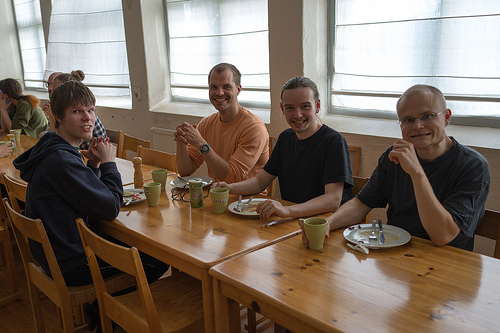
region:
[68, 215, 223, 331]
light brown wooden chair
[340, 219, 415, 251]
circular white plate on wooden table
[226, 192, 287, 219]
circular white plate on wooden table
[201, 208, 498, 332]
light brown rectangular wooden table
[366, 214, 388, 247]
silver metal knife and fork on white plate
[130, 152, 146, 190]
light brown wooden salt shaker on wooden table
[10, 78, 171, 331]
man wearing blue jacket and jeans sitting at wooden table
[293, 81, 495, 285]
man sitting at table holding cup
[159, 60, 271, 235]
man in light orange shirt sitting at wooden table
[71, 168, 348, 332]
rectangular light brown wooden table next to table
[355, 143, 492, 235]
the shirt is black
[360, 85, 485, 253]
the man has glasses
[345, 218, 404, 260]
the plate is on the table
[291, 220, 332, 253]
the cup is brown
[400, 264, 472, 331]
shadow is on the table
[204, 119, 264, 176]
the shirt is orange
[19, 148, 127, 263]
the jumper is blue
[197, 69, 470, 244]
the people are sitted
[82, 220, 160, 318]
the chair is wooden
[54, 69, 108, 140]
the woman is sitted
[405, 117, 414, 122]
The lens of glasses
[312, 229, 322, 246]
A cup on the table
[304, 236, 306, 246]
Fingers wrapped around a cup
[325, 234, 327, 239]
A thumb on the cup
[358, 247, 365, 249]
Paper napkin on the table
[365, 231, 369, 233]
Left over sauce on the plate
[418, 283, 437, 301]
Shadow cast by man on the table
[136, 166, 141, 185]
A salt shaker on the table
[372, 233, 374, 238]
A fork on the plate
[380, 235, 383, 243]
A knife on the plate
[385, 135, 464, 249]
A man has his elbow on a table.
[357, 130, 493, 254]
A man is wearing a dark shirt.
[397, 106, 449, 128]
A man is wearing glasses.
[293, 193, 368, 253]
A man has his hand on a cup.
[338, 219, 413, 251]
A plate is sitting on a table.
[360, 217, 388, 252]
A knife and fork are sitting on a plate.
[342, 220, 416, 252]
The color of a plate is white.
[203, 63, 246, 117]
A man is smiling.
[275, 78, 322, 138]
A woman is smiling.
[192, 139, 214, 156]
A man is wearing a watch.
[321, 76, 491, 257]
this is a man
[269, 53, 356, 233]
this is a man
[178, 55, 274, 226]
this is a man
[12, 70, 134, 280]
this is a man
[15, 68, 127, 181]
this is a man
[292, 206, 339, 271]
this is a cup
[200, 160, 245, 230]
this is a cup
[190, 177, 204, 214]
this is a cup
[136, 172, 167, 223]
this is a cup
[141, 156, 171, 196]
this is a cup